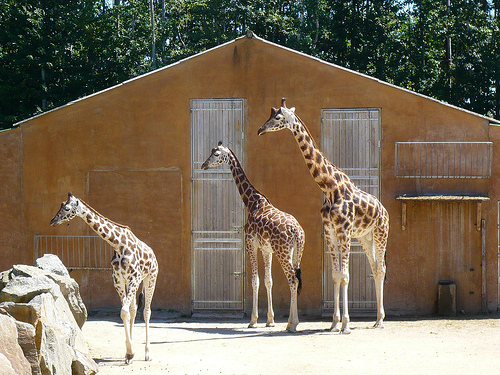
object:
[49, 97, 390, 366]
family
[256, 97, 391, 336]
giraffes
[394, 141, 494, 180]
railing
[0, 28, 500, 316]
building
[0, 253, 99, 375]
pile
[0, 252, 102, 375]
rocks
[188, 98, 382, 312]
two doors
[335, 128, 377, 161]
open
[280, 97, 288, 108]
horn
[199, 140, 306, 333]
female giraffe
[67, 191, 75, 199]
horn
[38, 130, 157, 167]
wall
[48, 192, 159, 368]
giraffe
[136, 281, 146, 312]
tail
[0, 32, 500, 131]
roof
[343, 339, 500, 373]
ground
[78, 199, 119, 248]
long neck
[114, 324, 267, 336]
shadow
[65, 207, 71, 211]
left eye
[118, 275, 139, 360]
front legs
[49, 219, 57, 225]
nose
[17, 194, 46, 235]
left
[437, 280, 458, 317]
box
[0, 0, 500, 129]
trees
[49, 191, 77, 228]
head